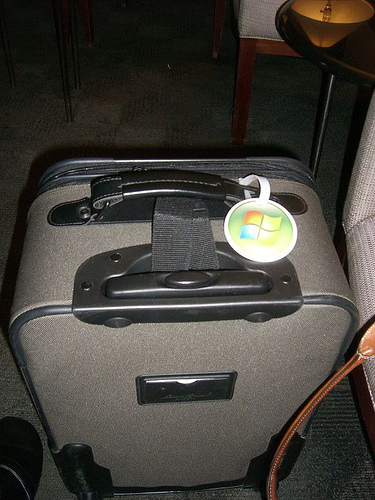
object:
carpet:
[8, 38, 226, 142]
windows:
[239, 208, 284, 243]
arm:
[340, 93, 374, 235]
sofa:
[333, 87, 375, 464]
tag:
[224, 197, 298, 263]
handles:
[92, 158, 273, 300]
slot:
[134, 370, 238, 405]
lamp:
[289, 8, 363, 48]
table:
[274, 0, 375, 88]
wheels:
[71, 461, 304, 499]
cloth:
[342, 92, 375, 410]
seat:
[345, 214, 375, 409]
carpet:
[96, 112, 148, 135]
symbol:
[241, 201, 281, 250]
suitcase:
[8, 156, 361, 500]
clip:
[237, 173, 272, 203]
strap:
[271, 369, 353, 461]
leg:
[230, 56, 254, 144]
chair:
[230, 0, 302, 147]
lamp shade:
[288, 0, 375, 25]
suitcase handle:
[87, 170, 259, 212]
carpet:
[0, 0, 374, 499]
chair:
[334, 85, 374, 461]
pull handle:
[104, 270, 272, 297]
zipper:
[42, 160, 286, 174]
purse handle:
[265, 322, 375, 499]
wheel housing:
[52, 443, 116, 499]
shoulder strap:
[151, 194, 219, 273]